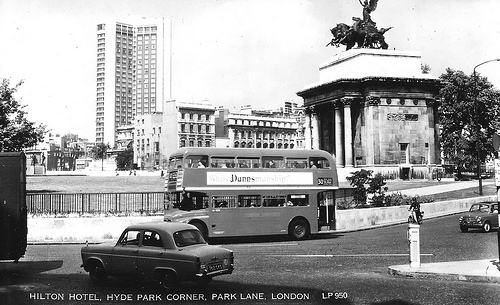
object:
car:
[81, 221, 236, 289]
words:
[25, 292, 37, 301]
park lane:
[214, 292, 272, 303]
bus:
[162, 147, 340, 239]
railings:
[23, 189, 165, 218]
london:
[271, 293, 313, 302]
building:
[97, 14, 170, 159]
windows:
[115, 26, 155, 129]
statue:
[323, 0, 389, 50]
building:
[297, 47, 443, 165]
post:
[472, 53, 500, 185]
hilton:
[26, 291, 66, 302]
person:
[408, 197, 426, 224]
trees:
[345, 169, 415, 209]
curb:
[352, 200, 494, 231]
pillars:
[301, 102, 353, 168]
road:
[0, 207, 497, 305]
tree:
[429, 66, 499, 180]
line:
[262, 247, 434, 260]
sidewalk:
[389, 173, 496, 198]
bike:
[408, 207, 423, 224]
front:
[78, 237, 123, 275]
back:
[195, 250, 235, 275]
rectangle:
[204, 172, 315, 190]